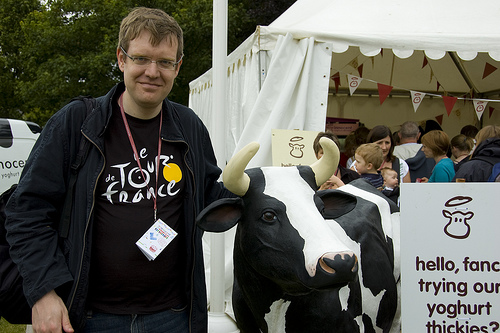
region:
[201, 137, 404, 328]
Black and white cow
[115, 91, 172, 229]
The lanyard is red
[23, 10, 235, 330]
Man wearing a black sweater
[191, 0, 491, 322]
The tent is white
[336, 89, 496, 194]
People inside the tent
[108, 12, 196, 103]
The man is wearing glasses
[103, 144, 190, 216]
White writing on the shirt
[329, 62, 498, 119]
The flags are red and white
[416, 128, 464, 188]
Women wearing a blue shirt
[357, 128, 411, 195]
Women holding a baby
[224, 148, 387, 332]
A black and white cow made of plastic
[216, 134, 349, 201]
Two white horns on the cow's head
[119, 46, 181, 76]
Reading glasses on the man's face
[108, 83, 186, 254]
A red lanyard around the man's neck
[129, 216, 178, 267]
An ID on the man's red lanyard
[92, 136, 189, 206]
The shirt says "Tour de France"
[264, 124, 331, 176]
A small cow head on the white sign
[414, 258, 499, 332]
Brown writing on the white poster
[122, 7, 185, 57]
The man's hair is short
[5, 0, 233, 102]
Trees behind the tent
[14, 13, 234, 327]
this is a person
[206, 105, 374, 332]
this is a cow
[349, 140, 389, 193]
this is a child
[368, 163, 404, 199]
this is a child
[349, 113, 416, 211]
this is a person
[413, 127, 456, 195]
this is a person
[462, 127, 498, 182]
this is a person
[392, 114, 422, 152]
this is a person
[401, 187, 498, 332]
this is a sign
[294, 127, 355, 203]
this is a horn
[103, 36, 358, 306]
a man next to a cow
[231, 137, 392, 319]
a white and black cow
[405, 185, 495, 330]
a black and white sign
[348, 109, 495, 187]
people under a tent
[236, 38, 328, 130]
a white tent for cover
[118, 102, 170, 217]
a red lanyard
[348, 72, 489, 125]
triangles on a string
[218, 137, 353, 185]
horns on a cow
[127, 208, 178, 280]
a card hanging on a lanyard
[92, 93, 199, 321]
a black and white tshirt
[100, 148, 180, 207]
logo on man's shirt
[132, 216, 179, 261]
visitor's pass hanging from man's neck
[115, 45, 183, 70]
glasses on man's face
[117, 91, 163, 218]
lanyard hanging from man's neck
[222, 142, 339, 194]
horns on plastic cow's head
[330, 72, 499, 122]
red and white banner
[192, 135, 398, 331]
black and white plastic cow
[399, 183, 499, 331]
white advertising sign with cow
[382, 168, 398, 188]
little baby's head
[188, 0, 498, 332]
white tent with people inside